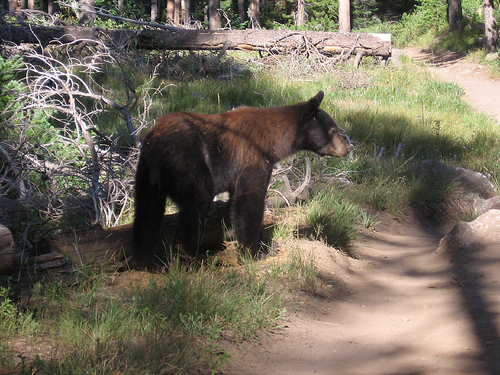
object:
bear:
[128, 89, 352, 269]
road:
[228, 220, 498, 375]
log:
[50, 224, 133, 276]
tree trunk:
[0, 22, 394, 61]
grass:
[0, 288, 13, 323]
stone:
[434, 209, 499, 254]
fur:
[235, 108, 281, 138]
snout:
[347, 142, 354, 151]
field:
[0, 0, 499, 375]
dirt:
[387, 48, 499, 118]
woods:
[0, 223, 17, 254]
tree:
[0, 22, 391, 59]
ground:
[0, 0, 499, 374]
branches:
[0, 88, 122, 110]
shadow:
[192, 115, 282, 178]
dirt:
[220, 226, 499, 373]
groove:
[400, 211, 470, 246]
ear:
[306, 89, 325, 112]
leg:
[234, 164, 269, 245]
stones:
[326, 283, 330, 287]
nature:
[0, 0, 498, 375]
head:
[304, 87, 356, 162]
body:
[127, 106, 277, 262]